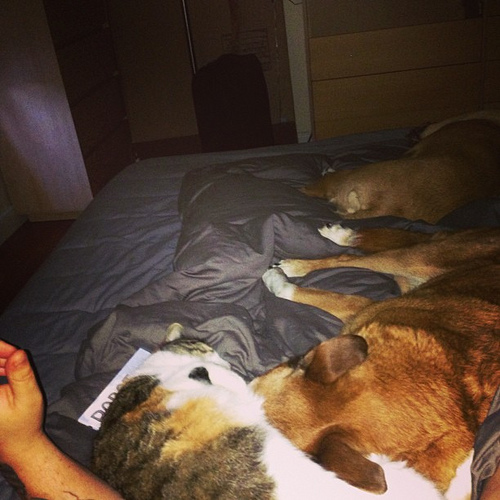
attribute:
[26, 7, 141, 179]
panels — wood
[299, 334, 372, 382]
ear — brown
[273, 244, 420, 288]
leg — white, brown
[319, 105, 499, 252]
dog — sleeping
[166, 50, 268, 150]
suitcase — black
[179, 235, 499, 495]
dog — brown, sleeping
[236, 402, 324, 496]
belly — white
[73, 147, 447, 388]
blanket — grey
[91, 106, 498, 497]
animals — several, sleeping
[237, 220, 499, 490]
dog — brown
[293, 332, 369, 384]
ear — brown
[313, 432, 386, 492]
ear — brown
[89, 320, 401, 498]
cat — multi-colored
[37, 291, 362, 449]
pillow — grey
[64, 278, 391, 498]
cat — sleeping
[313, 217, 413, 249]
leg — brown, white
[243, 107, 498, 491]
dogs — laying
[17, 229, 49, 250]
carpet — dark, flooring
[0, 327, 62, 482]
hand — human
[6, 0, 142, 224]
dresser — tan, wood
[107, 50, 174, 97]
wall — white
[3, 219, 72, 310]
carpet — brown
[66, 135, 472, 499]
comforter — blue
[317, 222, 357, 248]
paw — white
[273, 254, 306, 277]
paw — white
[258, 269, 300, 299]
paw — white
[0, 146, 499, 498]
blanket — gray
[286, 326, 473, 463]
dog — sleeping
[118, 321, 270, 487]
cat — sleeping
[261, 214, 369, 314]
paws — white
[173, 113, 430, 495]
dog — brown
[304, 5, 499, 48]
panel — tan, wood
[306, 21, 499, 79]
panel — tan, wood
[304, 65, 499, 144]
panel — tan, wood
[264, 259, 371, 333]
leg — brown, white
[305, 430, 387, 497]
ear — brown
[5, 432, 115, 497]
arm — human